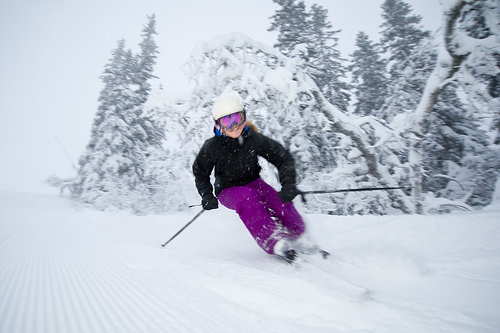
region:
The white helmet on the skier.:
[206, 95, 242, 115]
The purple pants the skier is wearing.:
[222, 180, 312, 245]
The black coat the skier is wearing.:
[190, 130, 285, 190]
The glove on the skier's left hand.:
[195, 191, 215, 202]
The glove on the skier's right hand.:
[276, 185, 296, 200]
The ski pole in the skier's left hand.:
[162, 185, 217, 245]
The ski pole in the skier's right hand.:
[293, 181, 412, 204]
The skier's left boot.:
[254, 230, 301, 262]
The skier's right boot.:
[292, 235, 319, 255]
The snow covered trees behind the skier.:
[69, 20, 493, 228]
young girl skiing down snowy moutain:
[194, 97, 326, 271]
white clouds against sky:
[3, 15, 78, 150]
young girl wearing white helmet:
[213, 96, 242, 119]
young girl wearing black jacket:
[194, 142, 286, 174]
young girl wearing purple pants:
[233, 184, 279, 228]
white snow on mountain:
[13, 207, 145, 319]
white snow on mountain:
[113, 272, 470, 327]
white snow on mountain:
[357, 227, 474, 312]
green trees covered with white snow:
[309, 40, 485, 182]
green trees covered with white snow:
[102, 38, 349, 94]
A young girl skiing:
[177, 99, 340, 255]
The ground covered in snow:
[9, 189, 498, 329]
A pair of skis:
[233, 236, 417, 305]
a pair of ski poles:
[146, 177, 430, 257]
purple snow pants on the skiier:
[211, 185, 326, 250]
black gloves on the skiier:
[195, 191, 306, 216]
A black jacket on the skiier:
[188, 127, 308, 197]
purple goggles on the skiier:
[216, 109, 252, 127]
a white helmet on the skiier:
[195, 90, 252, 119]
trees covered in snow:
[102, 48, 498, 236]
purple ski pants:
[133, 177, 336, 268]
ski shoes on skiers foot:
[192, 224, 392, 294]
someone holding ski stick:
[148, 176, 243, 276]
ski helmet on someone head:
[169, 82, 320, 178]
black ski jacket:
[175, 107, 343, 255]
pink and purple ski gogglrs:
[198, 81, 294, 175]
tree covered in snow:
[66, 33, 186, 233]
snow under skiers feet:
[193, 185, 448, 320]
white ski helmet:
[186, 54, 333, 166]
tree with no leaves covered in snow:
[266, 41, 496, 226]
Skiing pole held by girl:
[160, 190, 220, 245]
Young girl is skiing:
[190, 86, 330, 256]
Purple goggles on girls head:
[211, 107, 246, 127]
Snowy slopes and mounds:
[0, 192, 497, 322]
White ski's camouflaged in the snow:
[190, 235, 370, 295]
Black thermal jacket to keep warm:
[185, 125, 295, 205]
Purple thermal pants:
[215, 175, 305, 255]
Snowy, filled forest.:
[37, 0, 497, 205]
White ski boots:
[272, 231, 318, 261]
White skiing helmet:
[210, 93, 255, 140]